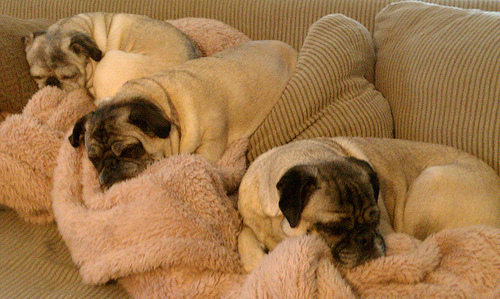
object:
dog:
[22, 12, 197, 101]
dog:
[68, 40, 297, 188]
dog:
[238, 135, 499, 273]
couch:
[0, 0, 496, 297]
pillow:
[373, 1, 499, 177]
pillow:
[246, 14, 393, 163]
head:
[275, 158, 387, 268]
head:
[68, 97, 172, 186]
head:
[22, 29, 102, 90]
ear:
[276, 166, 318, 228]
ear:
[130, 104, 171, 138]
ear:
[71, 33, 102, 61]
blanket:
[0, 17, 495, 297]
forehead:
[327, 171, 375, 215]